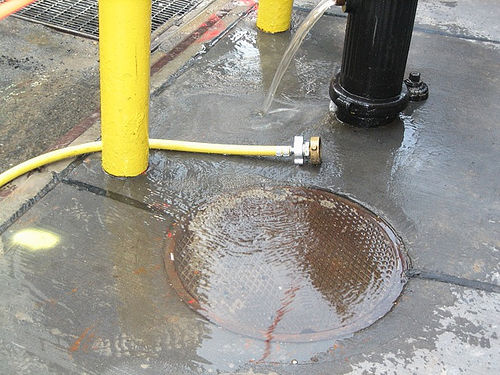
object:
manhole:
[157, 174, 425, 351]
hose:
[0, 123, 321, 207]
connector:
[283, 133, 326, 168]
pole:
[89, 0, 157, 182]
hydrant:
[321, 0, 433, 129]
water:
[258, 1, 338, 116]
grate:
[5, 2, 225, 57]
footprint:
[85, 313, 217, 364]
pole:
[243, 0, 302, 42]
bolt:
[401, 70, 434, 102]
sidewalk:
[15, 1, 500, 375]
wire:
[0, 1, 34, 22]